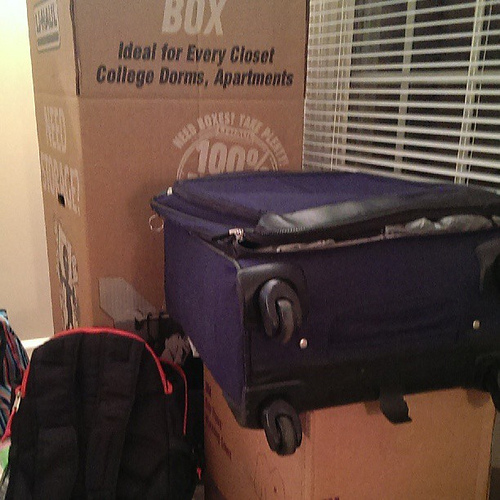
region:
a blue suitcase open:
[151, 102, 499, 459]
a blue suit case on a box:
[125, 105, 495, 442]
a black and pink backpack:
[8, 252, 243, 493]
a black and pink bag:
[5, 267, 224, 486]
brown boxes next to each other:
[47, 55, 496, 426]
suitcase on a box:
[100, 82, 424, 495]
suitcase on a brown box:
[147, 127, 494, 477]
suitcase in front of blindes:
[167, 57, 492, 445]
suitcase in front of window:
[139, 107, 485, 446]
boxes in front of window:
[29, 60, 483, 497]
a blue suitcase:
[134, 144, 498, 455]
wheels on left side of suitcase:
[231, 250, 336, 470]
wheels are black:
[235, 272, 335, 470]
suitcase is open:
[230, 187, 497, 271]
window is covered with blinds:
[295, 7, 497, 185]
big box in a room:
[25, 1, 315, 323]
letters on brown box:
[71, 5, 312, 175]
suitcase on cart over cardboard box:
[150, 158, 498, 496]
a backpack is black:
[5, 304, 203, 492]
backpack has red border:
[14, 310, 186, 442]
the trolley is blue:
[225, 234, 380, 399]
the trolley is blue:
[210, 250, 262, 387]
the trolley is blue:
[248, 238, 326, 378]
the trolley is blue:
[251, 284, 303, 398]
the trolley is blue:
[234, 265, 286, 389]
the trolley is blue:
[190, 305, 365, 426]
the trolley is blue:
[232, 274, 342, 449]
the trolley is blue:
[231, 190, 295, 352]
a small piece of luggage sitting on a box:
[167, 162, 494, 498]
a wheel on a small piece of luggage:
[262, 280, 304, 348]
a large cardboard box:
[37, 2, 290, 172]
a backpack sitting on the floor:
[9, 317, 209, 499]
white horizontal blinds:
[316, 6, 488, 168]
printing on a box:
[93, 40, 297, 89]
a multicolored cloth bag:
[3, 311, 20, 420]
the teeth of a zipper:
[268, 224, 330, 234]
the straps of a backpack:
[29, 341, 144, 498]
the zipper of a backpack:
[11, 385, 20, 415]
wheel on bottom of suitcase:
[260, 299, 297, 344]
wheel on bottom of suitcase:
[257, 407, 306, 461]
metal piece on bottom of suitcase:
[291, 334, 316, 361]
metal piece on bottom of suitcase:
[459, 312, 481, 333]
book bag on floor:
[12, 327, 201, 497]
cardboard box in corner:
[34, 4, 271, 200]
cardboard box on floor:
[209, 421, 461, 498]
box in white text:
[167, 0, 233, 48]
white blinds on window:
[341, 5, 498, 182]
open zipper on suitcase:
[291, 212, 373, 249]